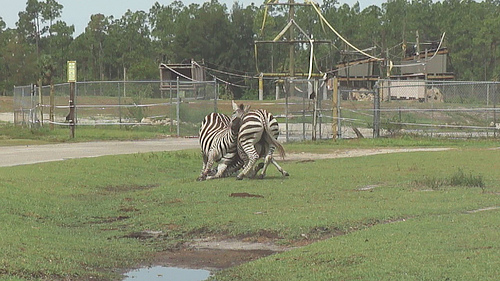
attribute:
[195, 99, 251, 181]
zebra — striped, fighting, charging, black, white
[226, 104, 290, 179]
zebra — facing downward, fat, fighting, striped, charging, black, white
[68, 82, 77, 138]
post — metal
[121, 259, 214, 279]
water — dark, puddle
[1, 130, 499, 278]
grass — weedy, long, green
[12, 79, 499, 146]
fence — chain-link, metal, connected, grey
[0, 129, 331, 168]
road — grey, concrete, walkway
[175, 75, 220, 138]
gate — open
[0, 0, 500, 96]
trees — distant, leafy, green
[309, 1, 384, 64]
cable — yellow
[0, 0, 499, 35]
sky — blue, clear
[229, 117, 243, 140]
snout — black